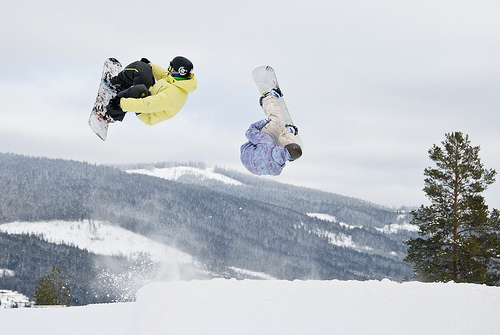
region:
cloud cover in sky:
[0, 0, 499, 205]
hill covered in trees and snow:
[1, 152, 418, 302]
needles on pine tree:
[410, 130, 498, 280]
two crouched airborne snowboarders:
[86, 55, 304, 176]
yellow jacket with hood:
[121, 61, 194, 124]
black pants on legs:
[108, 60, 153, 117]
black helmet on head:
[166, 56, 193, 78]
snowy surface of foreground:
[5, 279, 495, 334]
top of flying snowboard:
[252, 64, 297, 134]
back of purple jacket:
[241, 122, 288, 173]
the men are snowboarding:
[44, 18, 411, 284]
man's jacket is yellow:
[127, 58, 204, 140]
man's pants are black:
[89, 51, 165, 134]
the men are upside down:
[67, 30, 322, 184]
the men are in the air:
[70, 38, 351, 200]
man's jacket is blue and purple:
[220, 106, 298, 192]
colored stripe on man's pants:
[120, 65, 143, 79]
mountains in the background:
[3, 141, 495, 333]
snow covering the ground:
[0, 266, 498, 333]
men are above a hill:
[20, 9, 498, 328]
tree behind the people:
[417, 137, 482, 280]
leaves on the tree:
[416, 148, 454, 217]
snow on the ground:
[200, 290, 274, 327]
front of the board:
[73, 108, 115, 146]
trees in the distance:
[191, 194, 273, 252]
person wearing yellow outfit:
[89, 38, 219, 143]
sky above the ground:
[315, 8, 413, 112]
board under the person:
[246, 69, 326, 158]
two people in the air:
[71, 26, 380, 192]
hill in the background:
[160, 138, 242, 205]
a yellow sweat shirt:
[123, 85, 198, 123]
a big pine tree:
[383, 123, 493, 302]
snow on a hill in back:
[131, 160, 264, 212]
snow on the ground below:
[176, 280, 362, 333]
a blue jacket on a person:
[236, 127, 291, 182]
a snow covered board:
[248, 42, 280, 94]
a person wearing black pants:
[97, 48, 156, 113]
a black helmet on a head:
[166, 51, 201, 76]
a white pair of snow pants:
[263, 91, 288, 144]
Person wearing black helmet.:
[168, 53, 202, 91]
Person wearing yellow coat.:
[152, 78, 183, 128]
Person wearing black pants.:
[113, 61, 165, 138]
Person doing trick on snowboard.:
[90, 53, 157, 184]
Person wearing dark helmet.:
[279, 147, 311, 176]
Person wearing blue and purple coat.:
[244, 118, 283, 173]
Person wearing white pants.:
[265, 116, 300, 138]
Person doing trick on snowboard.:
[258, 63, 327, 213]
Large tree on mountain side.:
[421, 124, 482, 285]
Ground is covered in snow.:
[160, 287, 332, 329]